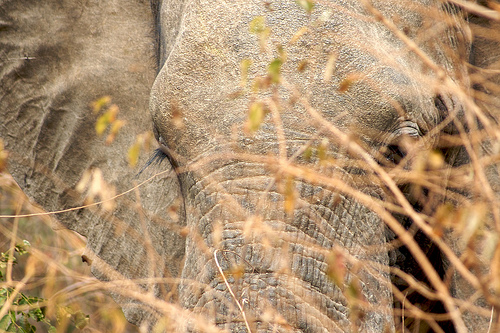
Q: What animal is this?
A: An elephant.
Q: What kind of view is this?
A: A close view.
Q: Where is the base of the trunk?
A: On the face of the elephant.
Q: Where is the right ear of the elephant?
A: On the right side.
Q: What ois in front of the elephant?
A: Dry weeds.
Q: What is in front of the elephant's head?
A: Branches/.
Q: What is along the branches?
A: Dried leaves.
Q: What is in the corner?
A: Green plant with droopy leaves.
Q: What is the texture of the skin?
A: Gray and tan skin with pebbly texture.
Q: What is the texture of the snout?
A: Wrinkled gray elephant snout.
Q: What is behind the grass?
A: Elephant head behind brown grass.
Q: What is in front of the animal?
A: Dry brown grass in front of animal.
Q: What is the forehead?
A: Light gray elephant forehead.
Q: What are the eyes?
A: Two dark elephant eyes.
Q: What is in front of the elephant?
A: Weeds growing in front of elephant.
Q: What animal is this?
A: Elephant.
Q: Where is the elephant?
A: In the brush.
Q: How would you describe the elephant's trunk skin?
A: Wrinkled and dry.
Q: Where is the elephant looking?
A: At the camera.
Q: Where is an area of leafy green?
A: Behind the elephants ear.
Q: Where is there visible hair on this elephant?
A: Eyelids.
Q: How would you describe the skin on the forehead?
A: Scaly.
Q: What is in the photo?
A: An elephant.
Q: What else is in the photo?
A: Grass.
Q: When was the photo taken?
A: Daytime.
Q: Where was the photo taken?
A: In the elephant's habitat.